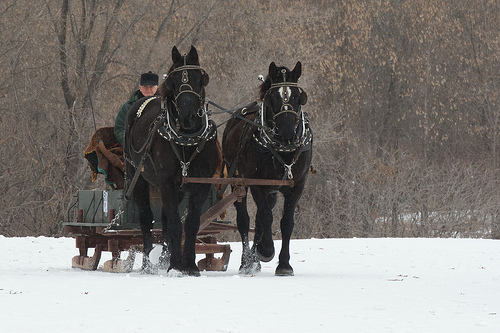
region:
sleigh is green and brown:
[54, 172, 241, 286]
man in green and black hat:
[116, 61, 163, 156]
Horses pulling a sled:
[56, 70, 378, 274]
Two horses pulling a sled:
[75, 47, 353, 281]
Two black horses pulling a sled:
[61, 40, 367, 294]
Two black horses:
[150, 53, 332, 251]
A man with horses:
[47, 42, 367, 297]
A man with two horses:
[81, 47, 331, 267]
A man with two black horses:
[70, 48, 349, 274]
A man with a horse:
[79, 31, 219, 197]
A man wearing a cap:
[121, 53, 176, 141]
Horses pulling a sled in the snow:
[41, 45, 380, 321]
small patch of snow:
[382, 195, 462, 225]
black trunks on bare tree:
[28, 61, 100, 116]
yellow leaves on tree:
[320, 31, 407, 88]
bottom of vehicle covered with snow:
[65, 245, 162, 269]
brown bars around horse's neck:
[175, 170, 312, 193]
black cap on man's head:
[129, 68, 175, 87]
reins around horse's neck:
[166, 66, 214, 140]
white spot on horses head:
[273, 80, 298, 115]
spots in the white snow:
[328, 250, 498, 302]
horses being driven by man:
[56, 32, 361, 287]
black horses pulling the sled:
[121, 35, 336, 289]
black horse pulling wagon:
[118, 32, 239, 253]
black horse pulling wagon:
[220, 38, 334, 273]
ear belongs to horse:
[169, 42, 181, 66]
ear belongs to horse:
[187, 43, 199, 59]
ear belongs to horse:
[268, 60, 278, 82]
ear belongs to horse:
[289, 60, 304, 80]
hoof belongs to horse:
[273, 261, 293, 275]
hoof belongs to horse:
[255, 239, 275, 263]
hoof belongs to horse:
[178, 260, 198, 278]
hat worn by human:
[137, 68, 160, 85]